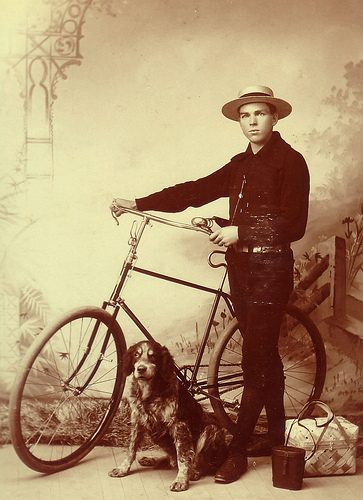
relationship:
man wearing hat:
[109, 82, 311, 483] [216, 83, 293, 125]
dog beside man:
[105, 336, 229, 491] [109, 82, 311, 483]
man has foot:
[109, 82, 311, 483] [212, 448, 251, 482]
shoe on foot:
[210, 450, 252, 483] [212, 448, 251, 482]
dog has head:
[105, 336, 229, 491] [120, 337, 174, 385]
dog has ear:
[105, 336, 229, 491] [158, 343, 175, 385]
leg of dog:
[162, 419, 195, 489] [114, 326, 234, 495]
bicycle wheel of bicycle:
[6, 301, 129, 476] [7, 195, 329, 476]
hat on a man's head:
[222, 83, 305, 122] [216, 77, 301, 151]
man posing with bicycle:
[109, 82, 311, 483] [7, 182, 358, 476]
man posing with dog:
[109, 82, 311, 483] [105, 335, 286, 491]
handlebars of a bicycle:
[105, 198, 263, 267] [6, 204, 338, 481]